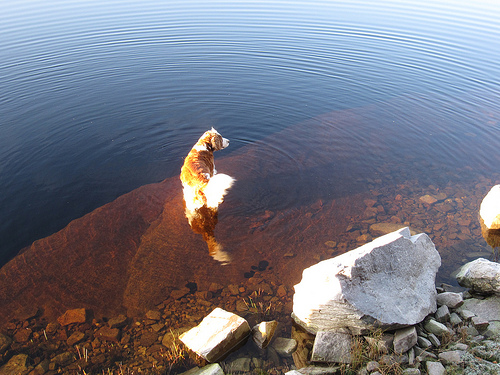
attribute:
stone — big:
[286, 222, 445, 345]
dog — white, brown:
[163, 115, 258, 262]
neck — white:
[191, 142, 209, 151]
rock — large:
[478, 180, 499, 239]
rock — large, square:
[290, 224, 441, 334]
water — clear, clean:
[31, 72, 489, 209]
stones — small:
[379, 277, 495, 373]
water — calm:
[0, 0, 497, 242]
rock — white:
[259, 227, 446, 349]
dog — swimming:
[180, 122, 245, 227]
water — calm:
[2, 2, 497, 373]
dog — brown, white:
[134, 109, 253, 269]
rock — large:
[178, 297, 265, 364]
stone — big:
[274, 213, 444, 338]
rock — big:
[288, 226, 451, 353]